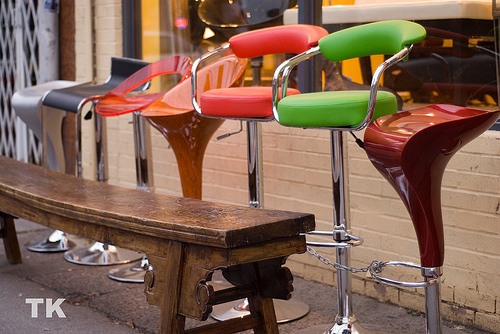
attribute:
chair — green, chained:
[271, 15, 423, 128]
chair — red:
[191, 16, 327, 123]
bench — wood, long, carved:
[1, 163, 317, 333]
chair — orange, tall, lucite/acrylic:
[87, 51, 194, 124]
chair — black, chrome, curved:
[43, 56, 152, 117]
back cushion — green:
[316, 16, 428, 59]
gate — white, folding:
[1, 2, 58, 164]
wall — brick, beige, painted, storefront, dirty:
[78, 97, 497, 315]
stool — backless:
[360, 105, 497, 333]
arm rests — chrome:
[269, 40, 317, 120]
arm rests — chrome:
[364, 50, 409, 131]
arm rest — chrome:
[190, 42, 232, 115]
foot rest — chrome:
[370, 259, 434, 288]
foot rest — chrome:
[300, 228, 360, 247]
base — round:
[68, 239, 142, 270]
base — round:
[208, 277, 313, 328]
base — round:
[26, 234, 71, 256]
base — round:
[107, 257, 151, 285]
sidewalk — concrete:
[1, 225, 499, 334]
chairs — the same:
[190, 21, 426, 333]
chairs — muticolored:
[7, 23, 492, 204]